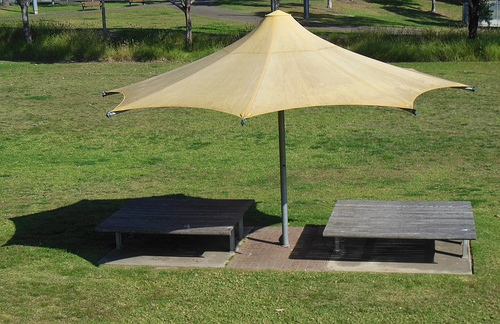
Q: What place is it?
A: It is a park.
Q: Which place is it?
A: It is a park.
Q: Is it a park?
A: Yes, it is a park.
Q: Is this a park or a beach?
A: It is a park.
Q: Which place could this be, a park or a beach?
A: It is a park.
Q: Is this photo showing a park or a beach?
A: It is showing a park.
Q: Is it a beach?
A: No, it is a park.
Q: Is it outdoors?
A: Yes, it is outdoors.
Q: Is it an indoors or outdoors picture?
A: It is outdoors.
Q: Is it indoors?
A: No, it is outdoors.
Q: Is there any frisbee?
A: No, there are no frisbees.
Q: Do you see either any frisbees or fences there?
A: No, there are no frisbees or fences.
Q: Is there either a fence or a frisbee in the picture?
A: No, there are no frisbees or fences.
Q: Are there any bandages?
A: No, there are no bandages.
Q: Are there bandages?
A: No, there are no bandages.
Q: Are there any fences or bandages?
A: No, there are no bandages or fences.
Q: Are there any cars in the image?
A: No, there are no cars.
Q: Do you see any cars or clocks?
A: No, there are no cars or clocks.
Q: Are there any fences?
A: No, there are no fences.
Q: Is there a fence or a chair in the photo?
A: No, there are no fences or chairs.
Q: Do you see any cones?
A: No, there are no cones.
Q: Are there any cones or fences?
A: No, there are no cones or fences.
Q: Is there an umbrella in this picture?
A: Yes, there is an umbrella.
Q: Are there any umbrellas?
A: Yes, there is an umbrella.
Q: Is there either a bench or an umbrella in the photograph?
A: Yes, there is an umbrella.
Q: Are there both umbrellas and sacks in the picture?
A: No, there is an umbrella but no sacks.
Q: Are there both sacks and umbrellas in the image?
A: No, there is an umbrella but no sacks.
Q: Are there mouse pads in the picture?
A: No, there are no mouse pads.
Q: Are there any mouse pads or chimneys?
A: No, there are no mouse pads or chimneys.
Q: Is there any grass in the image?
A: Yes, there is grass.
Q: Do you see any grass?
A: Yes, there is grass.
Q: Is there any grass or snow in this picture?
A: Yes, there is grass.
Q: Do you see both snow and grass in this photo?
A: No, there is grass but no snow.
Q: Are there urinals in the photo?
A: No, there are no urinals.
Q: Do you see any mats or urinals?
A: No, there are no urinals or mats.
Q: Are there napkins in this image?
A: No, there are no napkins.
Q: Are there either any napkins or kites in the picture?
A: No, there are no napkins or kites.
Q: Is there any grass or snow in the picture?
A: Yes, there is grass.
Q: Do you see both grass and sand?
A: No, there is grass but no sand.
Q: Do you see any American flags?
A: No, there are no American flags.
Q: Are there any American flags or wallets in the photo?
A: No, there are no American flags or wallets.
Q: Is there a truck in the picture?
A: No, there are no trucks.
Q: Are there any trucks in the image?
A: No, there are no trucks.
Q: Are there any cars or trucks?
A: No, there are no trucks or cars.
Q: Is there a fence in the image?
A: No, there are no fences.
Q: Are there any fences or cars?
A: No, there are no fences or cars.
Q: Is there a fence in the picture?
A: No, there are no fences.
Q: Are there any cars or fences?
A: No, there are no fences or cars.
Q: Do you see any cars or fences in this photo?
A: No, there are no fences or cars.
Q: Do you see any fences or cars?
A: No, there are no fences or cars.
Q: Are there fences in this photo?
A: No, there are no fences.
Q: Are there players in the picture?
A: No, there are no players.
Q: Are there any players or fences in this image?
A: No, there are no players or fences.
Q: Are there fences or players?
A: No, there are no players or fences.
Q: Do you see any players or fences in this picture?
A: No, there are no players or fences.